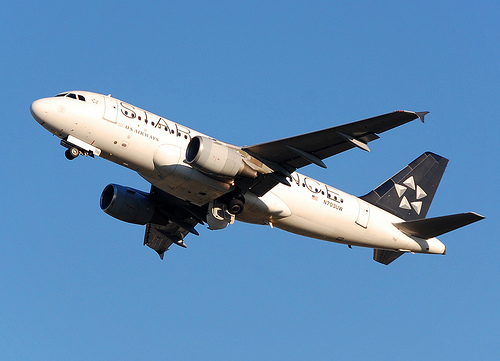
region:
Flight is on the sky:
[26, 55, 486, 304]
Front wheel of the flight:
[61, 141, 84, 166]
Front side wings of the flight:
[98, 92, 360, 234]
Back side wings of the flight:
[373, 148, 488, 284]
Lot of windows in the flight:
[123, 107, 348, 204]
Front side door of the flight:
[99, 92, 124, 125]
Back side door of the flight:
[356, 192, 374, 236]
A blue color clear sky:
[153, 17, 392, 85]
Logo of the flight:
[393, 176, 431, 216]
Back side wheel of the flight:
[223, 193, 253, 225]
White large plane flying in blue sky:
[30, 83, 488, 263]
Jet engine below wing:
[185, 133, 242, 175]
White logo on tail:
[392, 170, 430, 215]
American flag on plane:
[308, 192, 318, 202]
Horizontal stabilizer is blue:
[392, 207, 486, 243]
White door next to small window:
[101, 93, 119, 128]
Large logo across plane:
[117, 95, 344, 205]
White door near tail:
[352, 193, 374, 232]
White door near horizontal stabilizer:
[352, 198, 373, 230]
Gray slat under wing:
[332, 128, 376, 153]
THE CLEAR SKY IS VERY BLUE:
[1, 2, 498, 359]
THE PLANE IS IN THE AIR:
[20, 81, 491, 303]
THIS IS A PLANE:
[24, 87, 486, 282]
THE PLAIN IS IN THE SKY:
[14, 82, 489, 302]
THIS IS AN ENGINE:
[176, 128, 256, 183]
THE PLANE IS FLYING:
[18, 84, 480, 283]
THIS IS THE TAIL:
[355, 144, 487, 270]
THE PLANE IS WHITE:
[28, 85, 486, 282]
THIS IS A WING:
[241, 95, 431, 205]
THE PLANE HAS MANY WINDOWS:
[122, 105, 344, 206]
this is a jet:
[44, 91, 484, 243]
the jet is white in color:
[298, 208, 337, 233]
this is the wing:
[234, 120, 384, 152]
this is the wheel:
[59, 142, 92, 165]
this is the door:
[105, 90, 119, 125]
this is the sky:
[178, 5, 438, 75]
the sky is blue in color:
[158, 272, 300, 351]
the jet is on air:
[82, 105, 455, 254]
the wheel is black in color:
[224, 194, 244, 214]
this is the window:
[68, 91, 76, 100]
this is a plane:
[30, 78, 475, 270]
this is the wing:
[290, 100, 437, 147]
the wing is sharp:
[291, 94, 431, 149]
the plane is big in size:
[22, 90, 494, 268]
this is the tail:
[371, 141, 478, 230]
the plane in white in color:
[66, 103, 94, 132]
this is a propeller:
[180, 136, 247, 174]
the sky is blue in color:
[182, 4, 317, 99]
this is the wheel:
[63, 146, 83, 158]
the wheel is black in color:
[378, 149, 451, 206]